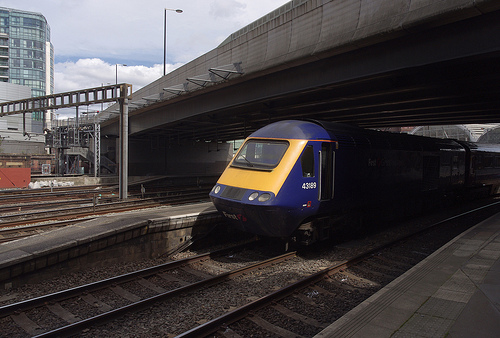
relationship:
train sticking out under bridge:
[205, 116, 497, 268] [47, 2, 497, 152]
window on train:
[299, 147, 315, 179] [205, 116, 497, 268]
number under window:
[299, 179, 317, 193] [299, 147, 315, 179]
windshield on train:
[233, 136, 288, 171] [205, 116, 497, 268]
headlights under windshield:
[206, 181, 216, 195] [233, 136, 288, 171]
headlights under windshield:
[209, 185, 219, 195] [233, 136, 288, 171]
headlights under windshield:
[245, 189, 265, 206] [233, 136, 288, 171]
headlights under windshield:
[257, 191, 269, 205] [233, 136, 288, 171]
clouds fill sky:
[50, 53, 181, 121] [2, 1, 288, 131]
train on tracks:
[205, 116, 497, 268] [4, 185, 498, 334]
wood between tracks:
[105, 280, 147, 307] [4, 185, 498, 334]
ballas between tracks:
[47, 196, 497, 336] [2, 229, 307, 334]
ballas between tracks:
[47, 196, 497, 336] [176, 190, 496, 333]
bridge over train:
[58, 1, 495, 167] [208, 114, 498, 255]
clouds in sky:
[1, 1, 290, 59] [2, 1, 288, 131]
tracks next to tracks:
[4, 62, 150, 199] [176, 190, 496, 333]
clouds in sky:
[50, 53, 181, 121] [2, 1, 288, 131]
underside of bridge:
[119, 49, 498, 146] [58, 1, 495, 167]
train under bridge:
[205, 116, 497, 268] [58, 1, 495, 167]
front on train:
[205, 127, 306, 225] [205, 116, 497, 268]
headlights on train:
[209, 185, 219, 195] [205, 116, 497, 268]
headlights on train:
[245, 189, 259, 202] [205, 116, 497, 268]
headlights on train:
[257, 191, 269, 205] [205, 116, 497, 268]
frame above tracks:
[5, 83, 135, 209] [2, 162, 258, 225]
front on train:
[205, 127, 306, 225] [208, 114, 498, 255]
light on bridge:
[171, 7, 181, 16] [58, 1, 495, 167]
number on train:
[299, 179, 317, 193] [205, 116, 497, 268]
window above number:
[299, 147, 315, 179] [295, 177, 317, 193]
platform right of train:
[312, 201, 495, 333] [208, 114, 498, 255]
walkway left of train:
[1, 199, 230, 267] [208, 114, 498, 255]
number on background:
[299, 179, 317, 193] [287, 172, 325, 202]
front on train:
[205, 127, 306, 225] [192, 106, 498, 243]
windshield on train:
[233, 136, 288, 171] [192, 106, 498, 243]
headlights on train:
[206, 180, 280, 208] [192, 106, 498, 243]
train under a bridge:
[205, 116, 497, 268] [121, 10, 469, 110]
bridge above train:
[58, 1, 495, 167] [181, 111, 467, 264]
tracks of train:
[18, 236, 185, 336] [192, 113, 445, 236]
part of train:
[213, 196, 260, 226] [179, 90, 383, 251]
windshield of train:
[233, 136, 288, 171] [193, 107, 403, 240]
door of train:
[317, 134, 338, 214] [192, 106, 498, 243]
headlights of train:
[257, 191, 269, 205] [185, 110, 464, 240]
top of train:
[245, 106, 334, 172] [208, 114, 498, 255]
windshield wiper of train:
[215, 138, 255, 169] [200, 110, 413, 244]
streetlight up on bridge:
[143, 3, 190, 72] [95, 0, 451, 132]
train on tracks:
[205, 116, 497, 268] [40, 247, 310, 334]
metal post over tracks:
[3, 165, 137, 223] [4, 62, 150, 199]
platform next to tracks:
[375, 217, 488, 335] [301, 218, 415, 316]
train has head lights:
[205, 116, 497, 268] [199, 171, 286, 228]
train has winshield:
[205, 116, 497, 268] [230, 123, 300, 183]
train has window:
[205, 116, 497, 268] [219, 115, 310, 182]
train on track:
[205, 116, 497, 268] [73, 210, 276, 327]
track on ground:
[115, 256, 201, 313] [81, 249, 287, 333]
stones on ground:
[140, 243, 240, 304] [99, 270, 269, 332]